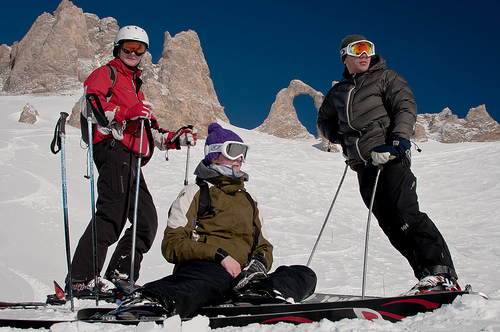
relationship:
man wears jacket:
[63, 24, 199, 295] [38, 59, 235, 179]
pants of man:
[348, 167, 452, 278] [313, 31, 456, 292]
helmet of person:
[111, 19, 176, 77] [69, 39, 197, 297]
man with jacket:
[63, 24, 199, 295] [83, 57, 153, 154]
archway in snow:
[274, 77, 332, 152] [1, 92, 484, 330]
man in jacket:
[63, 24, 199, 295] [163, 162, 277, 266]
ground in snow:
[273, 150, 314, 228] [448, 154, 488, 224]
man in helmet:
[61, 27, 164, 292] [112, 24, 149, 50]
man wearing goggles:
[132, 121, 315, 299] [202, 140, 252, 157]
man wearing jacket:
[61, 27, 164, 292] [73, 61, 188, 151]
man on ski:
[313, 31, 456, 292] [230, 283, 467, 330]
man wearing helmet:
[63, 24, 199, 295] [109, 20, 152, 45]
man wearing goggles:
[313, 31, 456, 292] [344, 33, 380, 51]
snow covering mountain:
[27, 113, 455, 257] [143, 23, 288, 135]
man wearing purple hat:
[109, 121, 319, 321] [200, 121, 249, 167]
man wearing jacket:
[319, 31, 488, 321] [315, 55, 418, 165]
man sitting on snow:
[109, 121, 319, 321] [1, 92, 484, 330]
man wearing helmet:
[63, 24, 199, 295] [110, 25, 150, 50]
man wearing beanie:
[109, 121, 319, 321] [202, 120, 243, 164]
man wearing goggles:
[313, 31, 456, 292] [338, 40, 375, 60]